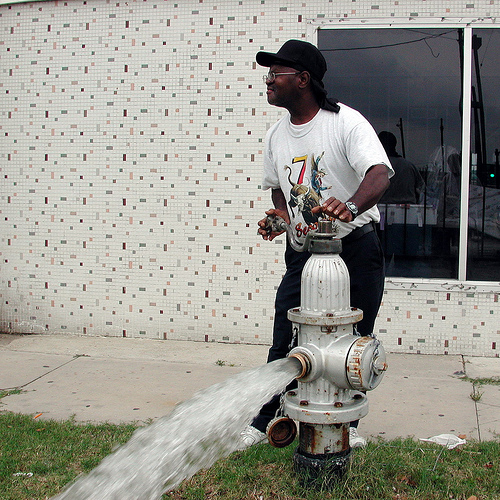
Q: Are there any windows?
A: Yes, there is a window.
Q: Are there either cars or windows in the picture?
A: Yes, there is a window.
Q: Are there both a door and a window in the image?
A: No, there is a window but no doors.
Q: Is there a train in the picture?
A: No, there are no trains.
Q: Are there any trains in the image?
A: No, there are no trains.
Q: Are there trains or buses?
A: No, there are no trains or buses.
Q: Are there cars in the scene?
A: No, there are no cars.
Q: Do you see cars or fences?
A: No, there are no cars or fences.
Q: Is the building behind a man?
A: Yes, the building is behind a man.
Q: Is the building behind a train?
A: No, the building is behind a man.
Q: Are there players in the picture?
A: No, there are no players.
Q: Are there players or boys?
A: No, there are no players or boys.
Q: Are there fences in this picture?
A: No, there are no fences.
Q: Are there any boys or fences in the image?
A: No, there are no fences or boys.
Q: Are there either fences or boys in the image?
A: No, there are no fences or boys.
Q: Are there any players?
A: No, there are no players.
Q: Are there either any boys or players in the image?
A: No, there are no players or boys.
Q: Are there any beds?
A: No, there are no beds.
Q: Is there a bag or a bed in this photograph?
A: No, there are no beds or bags.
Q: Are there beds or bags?
A: No, there are no beds or bags.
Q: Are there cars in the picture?
A: No, there are no cars.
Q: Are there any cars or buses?
A: No, there are no cars or buses.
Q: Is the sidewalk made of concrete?
A: Yes, the sidewalk is made of concrete.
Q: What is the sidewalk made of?
A: The sidewalk is made of concrete.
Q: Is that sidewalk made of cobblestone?
A: No, the sidewalk is made of concrete.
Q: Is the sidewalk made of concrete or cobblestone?
A: The sidewalk is made of concrete.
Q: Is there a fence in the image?
A: No, there are no fences.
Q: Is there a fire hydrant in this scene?
A: Yes, there is a fire hydrant.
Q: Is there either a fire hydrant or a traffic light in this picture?
A: Yes, there is a fire hydrant.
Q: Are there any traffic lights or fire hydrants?
A: Yes, there is a fire hydrant.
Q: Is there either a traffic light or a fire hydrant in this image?
A: Yes, there is a fire hydrant.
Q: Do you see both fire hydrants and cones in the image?
A: No, there is a fire hydrant but no cones.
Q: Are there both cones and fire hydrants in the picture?
A: No, there is a fire hydrant but no cones.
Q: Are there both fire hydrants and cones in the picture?
A: No, there is a fire hydrant but no cones.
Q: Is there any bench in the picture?
A: No, there are no benches.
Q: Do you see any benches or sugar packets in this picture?
A: No, there are no benches or sugar packets.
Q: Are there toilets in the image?
A: No, there are no toilets.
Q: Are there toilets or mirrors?
A: No, there are no toilets or mirrors.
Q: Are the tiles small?
A: Yes, the tiles are small.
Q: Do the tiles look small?
A: Yes, the tiles are small.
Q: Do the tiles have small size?
A: Yes, the tiles are small.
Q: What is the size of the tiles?
A: The tiles are small.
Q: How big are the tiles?
A: The tiles are small.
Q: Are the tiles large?
A: No, the tiles are small.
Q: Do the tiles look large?
A: No, the tiles are small.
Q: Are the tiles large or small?
A: The tiles are small.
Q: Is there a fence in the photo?
A: No, there are no fences.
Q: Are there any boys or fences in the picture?
A: No, there are no fences or boys.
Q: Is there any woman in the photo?
A: No, there are no women.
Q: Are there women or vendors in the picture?
A: No, there are no women or vendors.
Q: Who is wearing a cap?
A: The man is wearing a cap.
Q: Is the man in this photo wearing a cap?
A: Yes, the man is wearing a cap.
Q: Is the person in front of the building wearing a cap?
A: Yes, the man is wearing a cap.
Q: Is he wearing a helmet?
A: No, the man is wearing a cap.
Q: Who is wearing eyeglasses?
A: The man is wearing eyeglasses.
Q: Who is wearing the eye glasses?
A: The man is wearing eyeglasses.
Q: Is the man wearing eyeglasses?
A: Yes, the man is wearing eyeglasses.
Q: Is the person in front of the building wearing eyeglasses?
A: Yes, the man is wearing eyeglasses.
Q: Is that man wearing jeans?
A: No, the man is wearing eyeglasses.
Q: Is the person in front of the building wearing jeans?
A: No, the man is wearing eyeglasses.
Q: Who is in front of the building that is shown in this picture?
A: The man is in front of the building.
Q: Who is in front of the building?
A: The man is in front of the building.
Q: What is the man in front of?
A: The man is in front of the building.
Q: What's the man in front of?
A: The man is in front of the building.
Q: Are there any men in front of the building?
A: Yes, there is a man in front of the building.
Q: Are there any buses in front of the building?
A: No, there is a man in front of the building.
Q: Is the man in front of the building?
A: Yes, the man is in front of the building.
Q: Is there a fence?
A: No, there are no fences.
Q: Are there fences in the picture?
A: No, there are no fences.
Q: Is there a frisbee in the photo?
A: No, there are no frisbees.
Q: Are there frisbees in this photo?
A: No, there are no frisbees.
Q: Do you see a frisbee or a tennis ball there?
A: No, there are no frisbees or tennis balls.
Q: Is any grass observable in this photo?
A: Yes, there is grass.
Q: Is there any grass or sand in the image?
A: Yes, there is grass.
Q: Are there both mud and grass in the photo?
A: No, there is grass but no mud.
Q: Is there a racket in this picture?
A: No, there are no rackets.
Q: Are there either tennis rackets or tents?
A: No, there are no tennis rackets or tents.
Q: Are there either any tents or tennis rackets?
A: No, there are no tennis rackets or tents.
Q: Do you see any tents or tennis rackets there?
A: No, there are no tennis rackets or tents.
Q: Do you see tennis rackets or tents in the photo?
A: No, there are no tennis rackets or tents.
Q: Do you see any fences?
A: No, there are no fences.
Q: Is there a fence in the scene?
A: No, there are no fences.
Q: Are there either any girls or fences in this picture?
A: No, there are no fences or girls.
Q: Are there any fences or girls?
A: No, there are no fences or girls.